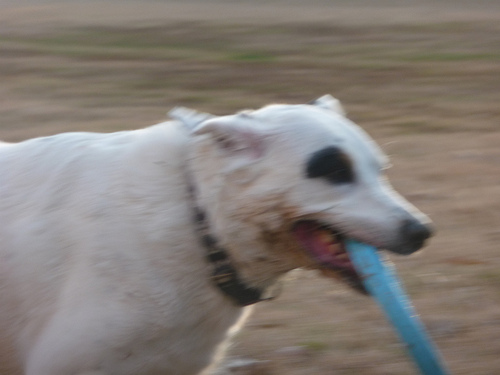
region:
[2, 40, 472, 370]
dog holding a frisbee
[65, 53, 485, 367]
dog holding a frisbee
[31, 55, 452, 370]
dog holding a frisbee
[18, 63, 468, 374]
dog holding a frisbee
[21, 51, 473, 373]
dog holding a frisbee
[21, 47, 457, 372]
dog holding a frisbee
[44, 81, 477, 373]
dog holding a frisbee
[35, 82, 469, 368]
dog holding a frisbee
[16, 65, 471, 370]
dog holding a frisbee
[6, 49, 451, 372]
dog holding a frisbee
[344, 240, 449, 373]
blue frisbee on the dog's mouth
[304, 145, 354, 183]
black patch around the dog's eye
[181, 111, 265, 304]
black collar around the dog's neck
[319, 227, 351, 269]
brown teeth in the dog's mouth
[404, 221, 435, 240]
black nose of a dog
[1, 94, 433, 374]
white dog carrying a frisbee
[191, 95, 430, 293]
head of a white dog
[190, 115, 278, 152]
right ear of a white dog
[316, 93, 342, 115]
left ear of a white dog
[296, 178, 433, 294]
mouth of a white dog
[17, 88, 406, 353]
This is a dog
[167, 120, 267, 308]
The dog is wearing a collar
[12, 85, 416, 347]
Only the right side of the dog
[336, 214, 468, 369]
There is a frisbee in the dog's mouth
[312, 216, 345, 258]
The dog's teeth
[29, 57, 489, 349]
The ground is covered in dirt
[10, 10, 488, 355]
The background of the image is out of focus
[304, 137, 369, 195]
The dog has black patch over eye.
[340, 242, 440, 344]
The dog is carrying a blue frisbee.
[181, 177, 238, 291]
Dog is wearing a black collar.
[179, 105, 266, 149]
The ear of the dog.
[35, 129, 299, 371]
The dog is white.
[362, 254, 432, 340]
The frisbee is blue.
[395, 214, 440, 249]
The dog has a nose.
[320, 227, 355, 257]
The teeth of the dog.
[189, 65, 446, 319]
head of a dog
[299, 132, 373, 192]
eye of a dog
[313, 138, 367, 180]
an eye of a dog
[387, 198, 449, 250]
nose of a dog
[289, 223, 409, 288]
mouth of a dog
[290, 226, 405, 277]
a mouth of a dog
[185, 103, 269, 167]
ear of a dog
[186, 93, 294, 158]
an ear of a dog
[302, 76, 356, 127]
ear of a dog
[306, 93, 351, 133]
an ear of a dog